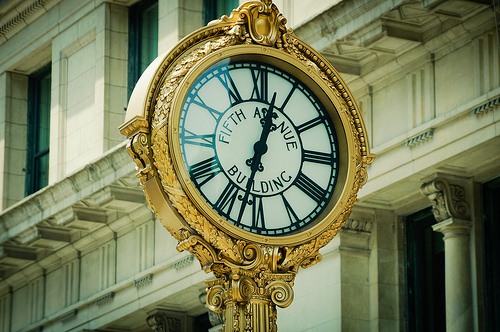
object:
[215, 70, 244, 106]
numeral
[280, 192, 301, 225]
roman numeral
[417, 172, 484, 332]
pillars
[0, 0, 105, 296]
building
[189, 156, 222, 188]
roman numeral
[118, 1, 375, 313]
golden frame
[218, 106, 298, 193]
writing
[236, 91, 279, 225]
hand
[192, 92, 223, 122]
numeral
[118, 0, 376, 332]
clock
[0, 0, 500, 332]
building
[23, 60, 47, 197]
window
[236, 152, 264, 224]
hand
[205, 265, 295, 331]
pole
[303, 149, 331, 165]
black numeral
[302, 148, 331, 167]
roman numeral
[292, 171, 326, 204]
numeral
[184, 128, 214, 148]
numeral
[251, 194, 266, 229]
numeral